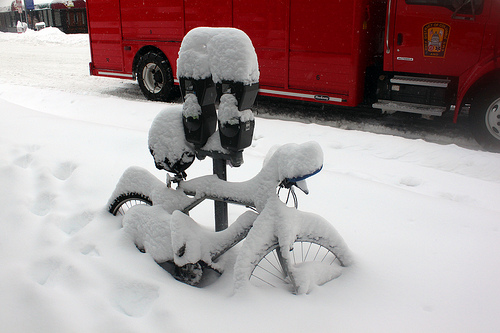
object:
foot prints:
[51, 158, 78, 182]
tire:
[129, 44, 177, 103]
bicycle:
[104, 105, 356, 295]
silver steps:
[370, 99, 446, 119]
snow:
[0, 24, 499, 332]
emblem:
[420, 22, 448, 58]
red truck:
[83, 0, 499, 155]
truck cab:
[372, 1, 499, 122]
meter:
[173, 27, 260, 169]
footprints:
[110, 279, 160, 319]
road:
[0, 33, 498, 333]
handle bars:
[275, 141, 329, 189]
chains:
[149, 56, 166, 73]